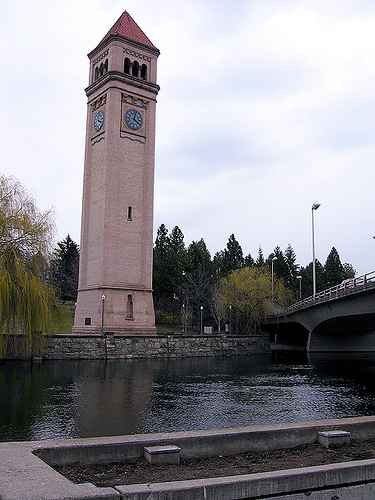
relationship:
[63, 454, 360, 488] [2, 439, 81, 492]
dirt by wall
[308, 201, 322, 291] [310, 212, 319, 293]
light on pole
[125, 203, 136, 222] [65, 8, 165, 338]
window in tower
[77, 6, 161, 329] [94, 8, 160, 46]
tower with roof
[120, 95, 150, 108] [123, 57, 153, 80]
border separating arches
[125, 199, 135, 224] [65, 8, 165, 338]
opening on tower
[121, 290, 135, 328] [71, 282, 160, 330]
lipstick in base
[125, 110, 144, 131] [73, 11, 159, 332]
clock on stone tower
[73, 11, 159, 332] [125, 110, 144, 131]
stone tower has clock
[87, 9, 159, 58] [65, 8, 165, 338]
roof on tower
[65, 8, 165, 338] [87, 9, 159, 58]
tower has roof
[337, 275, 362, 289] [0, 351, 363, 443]
car crossing river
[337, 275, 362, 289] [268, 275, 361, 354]
car on bridge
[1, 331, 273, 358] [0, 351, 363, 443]
wall facing river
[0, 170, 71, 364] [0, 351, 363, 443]
willow tree over river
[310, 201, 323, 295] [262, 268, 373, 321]
lamp post on bridge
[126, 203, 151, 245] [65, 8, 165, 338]
window on tower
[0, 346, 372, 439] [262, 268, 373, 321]
river under bridge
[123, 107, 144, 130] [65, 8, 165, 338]
clock on tower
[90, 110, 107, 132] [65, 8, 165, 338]
clock on tower